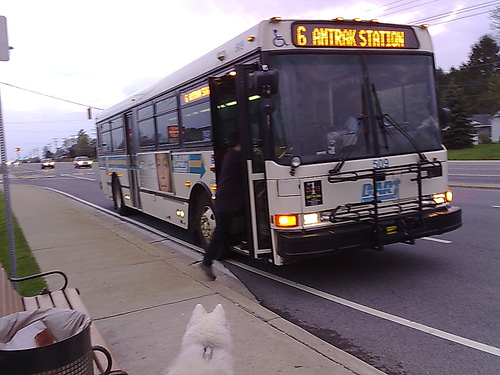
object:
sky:
[1, 3, 499, 161]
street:
[3, 158, 493, 368]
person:
[196, 131, 254, 284]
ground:
[201, 167, 497, 371]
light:
[300, 206, 326, 232]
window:
[263, 46, 458, 155]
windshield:
[267, 41, 453, 149]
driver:
[316, 87, 433, 190]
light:
[70, 98, 110, 128]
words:
[270, 8, 417, 59]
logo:
[341, 166, 428, 215]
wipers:
[295, 77, 455, 187]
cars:
[13, 144, 96, 172]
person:
[100, 47, 430, 227]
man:
[312, 84, 406, 152]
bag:
[17, 309, 68, 328]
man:
[184, 140, 293, 270]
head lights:
[56, 142, 109, 192]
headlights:
[270, 211, 315, 231]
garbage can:
[3, 311, 93, 372]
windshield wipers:
[370, 111, 424, 154]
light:
[179, 82, 209, 102]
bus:
[96, 18, 459, 268]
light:
[310, 27, 359, 43]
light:
[274, 213, 297, 229]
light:
[428, 191, 451, 203]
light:
[170, 209, 184, 218]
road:
[23, 154, 495, 368]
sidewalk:
[12, 184, 382, 373]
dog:
[169, 289, 235, 372]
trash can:
[3, 308, 95, 372]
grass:
[0, 190, 55, 298]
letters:
[296, 24, 403, 46]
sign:
[290, 19, 419, 49]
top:
[0, 308, 93, 356]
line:
[291, 271, 498, 364]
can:
[0, 308, 100, 373]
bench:
[0, 253, 126, 373]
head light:
[299, 210, 331, 229]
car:
[40, 158, 55, 168]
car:
[70, 153, 93, 168]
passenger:
[188, 126, 273, 276]